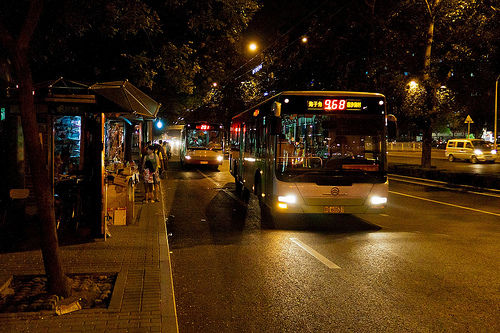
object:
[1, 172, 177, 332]
sidewalk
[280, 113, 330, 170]
reflections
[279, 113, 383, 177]
windshield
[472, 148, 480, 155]
headlight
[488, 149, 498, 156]
headlight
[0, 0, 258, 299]
tree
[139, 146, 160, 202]
people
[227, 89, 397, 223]
bus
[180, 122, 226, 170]
bus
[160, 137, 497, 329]
road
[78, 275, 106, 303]
rocks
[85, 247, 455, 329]
ground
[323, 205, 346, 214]
tag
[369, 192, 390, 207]
lights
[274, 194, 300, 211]
lights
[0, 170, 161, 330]
brick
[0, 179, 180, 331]
side walk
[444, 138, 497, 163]
car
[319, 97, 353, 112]
number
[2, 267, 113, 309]
square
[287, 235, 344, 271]
line